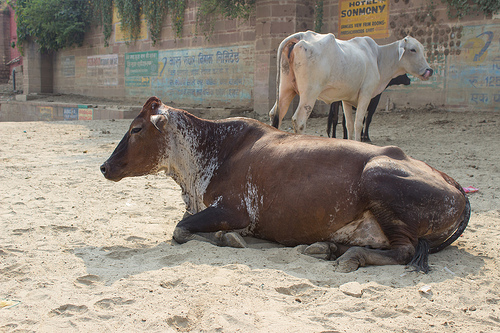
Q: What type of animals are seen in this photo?
A: Cattle.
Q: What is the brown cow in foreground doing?
A: Laying down.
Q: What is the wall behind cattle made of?
A: Brick.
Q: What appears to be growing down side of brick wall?
A: Vines.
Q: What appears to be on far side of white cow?
A: Calf.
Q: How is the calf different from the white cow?
A: Calf is black.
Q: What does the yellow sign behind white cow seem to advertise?
A: Hotel.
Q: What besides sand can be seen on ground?
A: Rocks.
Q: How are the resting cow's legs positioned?
A: Bent.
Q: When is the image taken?
A: Morning.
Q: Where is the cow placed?
A: On sand.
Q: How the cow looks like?
A: Good.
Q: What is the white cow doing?
A: Looking for food.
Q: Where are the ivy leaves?
A: Hanging on the wall.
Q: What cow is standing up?
A: White cow.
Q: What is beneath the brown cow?
A: Ground covered in sand.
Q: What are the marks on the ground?
A: Hoof prints in the san.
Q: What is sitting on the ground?
A: White and brown cow.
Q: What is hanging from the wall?
A: Vines.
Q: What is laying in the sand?
A: Brown cow.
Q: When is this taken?
A: Day time.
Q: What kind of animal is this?
A: Cow.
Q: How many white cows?
A: One.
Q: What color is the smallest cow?
A: Black.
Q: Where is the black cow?
A: Behind the white one.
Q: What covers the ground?
A: Sand.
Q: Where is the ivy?
A: On the wall.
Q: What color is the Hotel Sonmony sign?
A: Yellow.